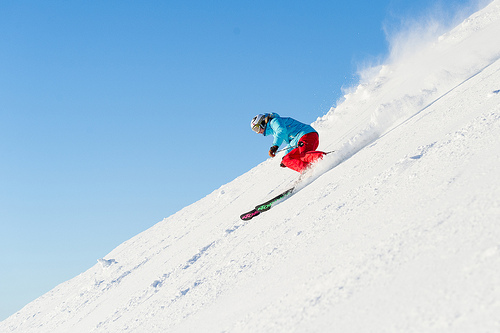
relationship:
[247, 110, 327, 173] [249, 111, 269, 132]
person wearing helmet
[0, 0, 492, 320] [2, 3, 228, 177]
cloud in blue sky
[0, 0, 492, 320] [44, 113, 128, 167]
cloud in sky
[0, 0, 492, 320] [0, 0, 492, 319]
cloud in blue sky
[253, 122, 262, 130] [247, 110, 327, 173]
goggle on person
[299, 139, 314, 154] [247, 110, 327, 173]
thigh of a person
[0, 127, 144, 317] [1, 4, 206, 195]
cloud in sky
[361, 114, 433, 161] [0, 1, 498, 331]
snow on ground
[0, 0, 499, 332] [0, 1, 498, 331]
snow on ground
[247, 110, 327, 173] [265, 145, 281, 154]
person has hand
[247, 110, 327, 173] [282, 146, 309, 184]
person has leg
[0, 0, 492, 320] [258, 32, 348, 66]
cloud in sky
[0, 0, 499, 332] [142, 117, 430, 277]
snow on ground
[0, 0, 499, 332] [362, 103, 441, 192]
snow on ground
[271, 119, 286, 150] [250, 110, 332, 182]
arm of person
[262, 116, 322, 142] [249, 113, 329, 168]
back of a person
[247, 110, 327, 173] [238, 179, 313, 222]
person on a ski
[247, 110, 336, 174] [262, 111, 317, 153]
person wearing a jacket